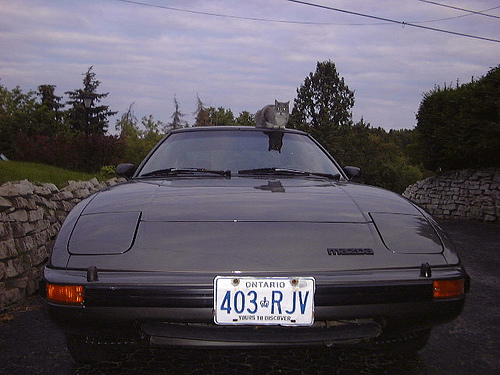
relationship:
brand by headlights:
[329, 233, 415, 282] [23, 175, 140, 313]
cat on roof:
[253, 96, 320, 130] [164, 102, 289, 139]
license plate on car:
[175, 261, 340, 322] [99, 110, 388, 304]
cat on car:
[253, 96, 320, 130] [99, 110, 388, 304]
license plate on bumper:
[175, 261, 340, 322] [110, 268, 387, 372]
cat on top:
[253, 96, 320, 130] [227, 122, 360, 188]